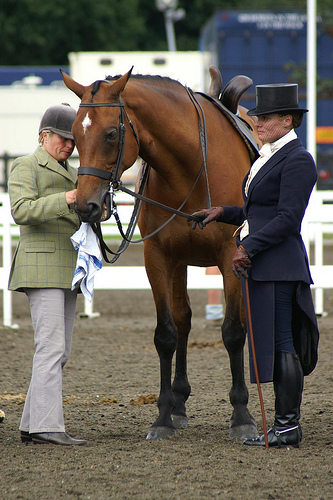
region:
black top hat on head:
[235, 80, 309, 128]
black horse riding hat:
[30, 95, 81, 144]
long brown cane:
[244, 278, 269, 462]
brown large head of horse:
[42, 59, 146, 227]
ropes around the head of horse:
[45, 78, 209, 254]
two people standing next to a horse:
[6, 54, 319, 473]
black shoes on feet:
[243, 425, 301, 451]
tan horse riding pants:
[12, 277, 76, 451]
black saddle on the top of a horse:
[180, 67, 276, 164]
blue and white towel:
[58, 214, 116, 327]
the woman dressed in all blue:
[187, 80, 321, 454]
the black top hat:
[246, 82, 309, 118]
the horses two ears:
[56, 66, 136, 96]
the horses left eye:
[104, 126, 117, 140]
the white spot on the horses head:
[77, 111, 94, 135]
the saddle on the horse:
[191, 61, 258, 139]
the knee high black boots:
[240, 348, 307, 454]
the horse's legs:
[136, 241, 256, 441]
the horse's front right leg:
[137, 237, 173, 440]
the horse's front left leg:
[208, 242, 256, 440]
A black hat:
[242, 73, 318, 130]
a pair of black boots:
[244, 347, 320, 462]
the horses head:
[56, 57, 162, 254]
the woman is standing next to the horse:
[221, 74, 321, 447]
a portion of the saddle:
[190, 54, 256, 151]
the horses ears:
[52, 65, 145, 96]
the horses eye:
[104, 118, 122, 146]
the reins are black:
[114, 81, 218, 249]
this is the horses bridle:
[73, 77, 141, 196]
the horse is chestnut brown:
[58, 63, 255, 447]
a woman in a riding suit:
[221, 83, 316, 446]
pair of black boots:
[252, 348, 316, 456]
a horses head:
[71, 64, 169, 215]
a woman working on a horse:
[12, 110, 102, 452]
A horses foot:
[143, 424, 186, 446]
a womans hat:
[243, 82, 299, 120]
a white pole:
[302, 0, 328, 77]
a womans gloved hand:
[188, 199, 227, 227]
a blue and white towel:
[62, 229, 113, 293]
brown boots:
[19, 422, 89, 457]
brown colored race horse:
[88, 57, 238, 304]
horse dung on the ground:
[108, 377, 171, 421]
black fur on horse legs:
[138, 299, 247, 441]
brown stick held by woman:
[233, 268, 280, 469]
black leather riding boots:
[224, 340, 317, 462]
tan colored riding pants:
[13, 294, 92, 433]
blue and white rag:
[75, 239, 137, 307]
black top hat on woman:
[246, 77, 309, 126]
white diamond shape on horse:
[76, 112, 104, 138]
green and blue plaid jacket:
[18, 157, 120, 298]